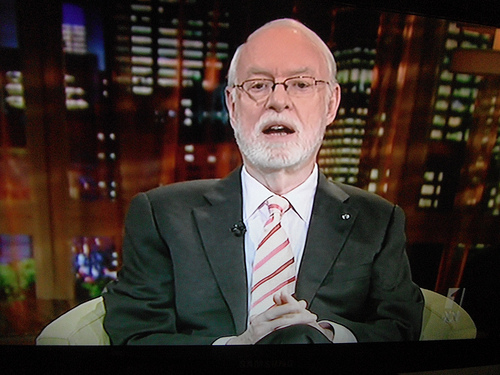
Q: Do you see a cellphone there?
A: No, there are no cell phones.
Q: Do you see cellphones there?
A: No, there are no cellphones.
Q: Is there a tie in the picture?
A: Yes, there is a tie.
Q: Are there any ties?
A: Yes, there is a tie.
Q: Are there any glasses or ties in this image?
A: Yes, there is a tie.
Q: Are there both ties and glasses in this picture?
A: Yes, there are both a tie and glasses.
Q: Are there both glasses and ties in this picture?
A: Yes, there are both a tie and glasses.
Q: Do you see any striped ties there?
A: Yes, there is a striped tie.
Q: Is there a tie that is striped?
A: Yes, there is a tie that is striped.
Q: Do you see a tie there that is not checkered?
A: Yes, there is a striped tie.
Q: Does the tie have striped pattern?
A: Yes, the tie is striped.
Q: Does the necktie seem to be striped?
A: Yes, the necktie is striped.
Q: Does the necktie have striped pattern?
A: Yes, the necktie is striped.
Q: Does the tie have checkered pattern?
A: No, the tie is striped.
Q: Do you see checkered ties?
A: No, there is a tie but it is striped.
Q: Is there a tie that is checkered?
A: No, there is a tie but it is striped.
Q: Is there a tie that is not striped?
A: No, there is a tie but it is striped.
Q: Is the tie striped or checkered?
A: The tie is striped.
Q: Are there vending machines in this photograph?
A: No, there are no vending machines.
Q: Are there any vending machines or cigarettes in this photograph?
A: No, there are no vending machines or cigarettes.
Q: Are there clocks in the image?
A: No, there are no clocks.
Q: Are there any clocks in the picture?
A: No, there are no clocks.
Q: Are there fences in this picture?
A: No, there are no fences.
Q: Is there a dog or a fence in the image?
A: No, there are no fences or dogs.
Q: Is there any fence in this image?
A: No, there are no fences.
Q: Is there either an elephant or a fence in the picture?
A: No, there are no fences or elephants.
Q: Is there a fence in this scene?
A: No, there are no fences.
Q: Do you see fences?
A: No, there are no fences.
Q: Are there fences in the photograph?
A: No, there are no fences.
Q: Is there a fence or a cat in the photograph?
A: No, there are no fences or cats.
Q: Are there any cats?
A: No, there are no cats.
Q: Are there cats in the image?
A: No, there are no cats.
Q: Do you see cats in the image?
A: No, there are no cats.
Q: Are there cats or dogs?
A: No, there are no cats or dogs.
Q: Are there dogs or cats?
A: No, there are no cats or dogs.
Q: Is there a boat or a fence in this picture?
A: No, there are no fences or boats.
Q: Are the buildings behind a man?
A: Yes, the buildings are behind a man.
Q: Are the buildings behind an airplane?
A: No, the buildings are behind a man.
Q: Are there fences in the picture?
A: No, there are no fences.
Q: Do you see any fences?
A: No, there are no fences.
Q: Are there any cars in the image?
A: No, there are no cars.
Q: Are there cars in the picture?
A: No, there are no cars.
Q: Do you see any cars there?
A: No, there are no cars.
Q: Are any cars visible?
A: No, there are no cars.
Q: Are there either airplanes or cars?
A: No, there are no cars or airplanes.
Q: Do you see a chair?
A: Yes, there is a chair.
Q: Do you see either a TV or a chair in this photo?
A: Yes, there is a chair.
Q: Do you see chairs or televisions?
A: Yes, there is a chair.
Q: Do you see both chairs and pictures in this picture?
A: No, there is a chair but no pictures.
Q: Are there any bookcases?
A: No, there are no bookcases.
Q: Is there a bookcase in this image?
A: No, there are no bookcases.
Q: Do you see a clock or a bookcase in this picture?
A: No, there are no bookcases or clocks.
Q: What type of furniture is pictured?
A: The furniture is a chair.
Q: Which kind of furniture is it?
A: The piece of furniture is a chair.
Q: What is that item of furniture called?
A: This is a chair.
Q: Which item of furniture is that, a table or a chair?
A: This is a chair.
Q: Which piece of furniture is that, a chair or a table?
A: This is a chair.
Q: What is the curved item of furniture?
A: The piece of furniture is a chair.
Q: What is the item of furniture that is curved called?
A: The piece of furniture is a chair.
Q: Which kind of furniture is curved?
A: The furniture is a chair.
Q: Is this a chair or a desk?
A: This is a chair.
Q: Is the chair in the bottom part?
A: Yes, the chair is in the bottom of the image.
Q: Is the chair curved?
A: Yes, the chair is curved.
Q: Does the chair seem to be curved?
A: Yes, the chair is curved.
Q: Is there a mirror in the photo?
A: No, there are no mirrors.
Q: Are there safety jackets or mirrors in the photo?
A: No, there are no mirrors or safety jackets.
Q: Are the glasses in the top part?
A: Yes, the glasses are in the top of the image.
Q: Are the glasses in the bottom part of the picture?
A: No, the glasses are in the top of the image.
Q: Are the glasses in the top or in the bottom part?
A: The glasses are in the top of the image.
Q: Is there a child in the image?
A: No, there are no children.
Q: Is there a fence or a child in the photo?
A: No, there are no children or fences.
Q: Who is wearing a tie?
A: The man is wearing a tie.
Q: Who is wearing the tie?
A: The man is wearing a tie.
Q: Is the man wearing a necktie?
A: Yes, the man is wearing a necktie.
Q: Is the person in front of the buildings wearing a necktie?
A: Yes, the man is wearing a necktie.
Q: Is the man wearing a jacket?
A: No, the man is wearing a necktie.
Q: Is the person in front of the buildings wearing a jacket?
A: No, the man is wearing a necktie.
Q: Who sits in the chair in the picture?
A: The man sits in the chair.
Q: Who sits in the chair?
A: The man sits in the chair.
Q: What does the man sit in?
A: The man sits in the chair.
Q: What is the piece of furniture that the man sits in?
A: The piece of furniture is a chair.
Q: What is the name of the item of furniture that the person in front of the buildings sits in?
A: The piece of furniture is a chair.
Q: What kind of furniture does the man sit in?
A: The man sits in the chair.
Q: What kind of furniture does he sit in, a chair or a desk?
A: The man sits in a chair.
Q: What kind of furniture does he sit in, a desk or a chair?
A: The man sits in a chair.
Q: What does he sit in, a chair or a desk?
A: The man sits in a chair.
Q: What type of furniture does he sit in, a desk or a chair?
A: The man sits in a chair.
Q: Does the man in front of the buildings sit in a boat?
A: No, the man sits in the chair.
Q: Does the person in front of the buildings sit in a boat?
A: No, the man sits in the chair.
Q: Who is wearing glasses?
A: The man is wearing glasses.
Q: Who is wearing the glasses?
A: The man is wearing glasses.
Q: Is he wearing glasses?
A: Yes, the man is wearing glasses.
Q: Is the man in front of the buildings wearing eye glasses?
A: No, the man is wearing glasses.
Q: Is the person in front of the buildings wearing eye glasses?
A: No, the man is wearing glasses.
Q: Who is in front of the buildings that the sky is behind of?
A: The man is in front of the buildings.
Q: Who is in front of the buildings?
A: The man is in front of the buildings.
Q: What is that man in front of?
A: The man is in front of the buildings.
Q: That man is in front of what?
A: The man is in front of the buildings.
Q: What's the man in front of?
A: The man is in front of the buildings.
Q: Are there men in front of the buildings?
A: Yes, there is a man in front of the buildings.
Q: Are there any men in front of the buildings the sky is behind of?
A: Yes, there is a man in front of the buildings.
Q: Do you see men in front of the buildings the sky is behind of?
A: Yes, there is a man in front of the buildings.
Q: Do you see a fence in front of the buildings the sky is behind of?
A: No, there is a man in front of the buildings.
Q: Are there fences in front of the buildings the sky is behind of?
A: No, there is a man in front of the buildings.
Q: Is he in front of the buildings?
A: Yes, the man is in front of the buildings.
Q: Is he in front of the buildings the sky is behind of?
A: Yes, the man is in front of the buildings.